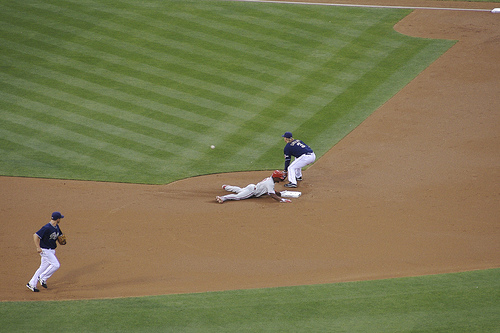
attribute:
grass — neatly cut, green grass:
[2, 0, 457, 184]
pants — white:
[27, 248, 58, 295]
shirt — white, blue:
[34, 221, 62, 249]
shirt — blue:
[286, 141, 312, 157]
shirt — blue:
[33, 225, 65, 248]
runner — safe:
[215, 170, 295, 204]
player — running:
[25, 210, 65, 292]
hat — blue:
[52, 211, 64, 219]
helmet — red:
[267, 169, 284, 181]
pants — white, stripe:
[22, 249, 58, 291]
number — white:
[294, 138, 306, 149]